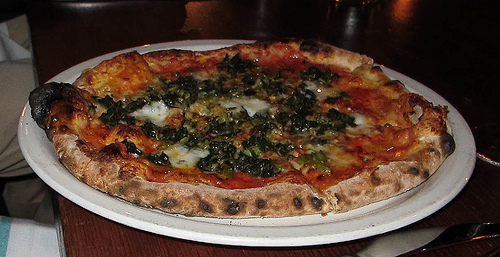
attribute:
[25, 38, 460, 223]
pizza — cooked, vegetable, chees, with spinach, baked, fresh, cheesy, greasy, well done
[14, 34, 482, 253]
dish — round, white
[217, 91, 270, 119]
cheese — white, melted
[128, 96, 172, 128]
cheese — white, melted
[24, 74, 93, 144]
crust — burnt